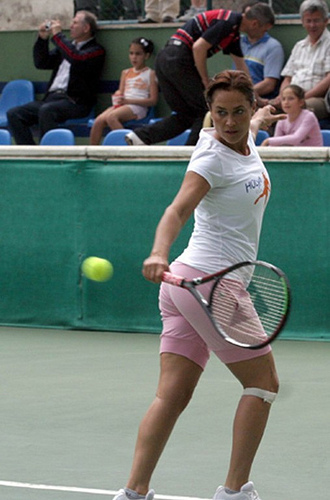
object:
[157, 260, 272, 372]
pink shorts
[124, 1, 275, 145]
man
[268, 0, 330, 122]
man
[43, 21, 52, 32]
camera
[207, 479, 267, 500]
white shoe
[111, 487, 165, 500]
white shoe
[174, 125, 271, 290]
t-shirt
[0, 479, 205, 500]
white line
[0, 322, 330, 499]
court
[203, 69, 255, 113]
hair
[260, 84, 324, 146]
girl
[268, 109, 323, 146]
pink shirt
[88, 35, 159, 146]
girl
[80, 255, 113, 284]
tennis ball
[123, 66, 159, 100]
shirt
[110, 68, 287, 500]
woman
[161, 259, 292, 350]
racket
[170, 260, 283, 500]
leg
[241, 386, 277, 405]
band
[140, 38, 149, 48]
hair bow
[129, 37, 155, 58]
hair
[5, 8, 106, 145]
man